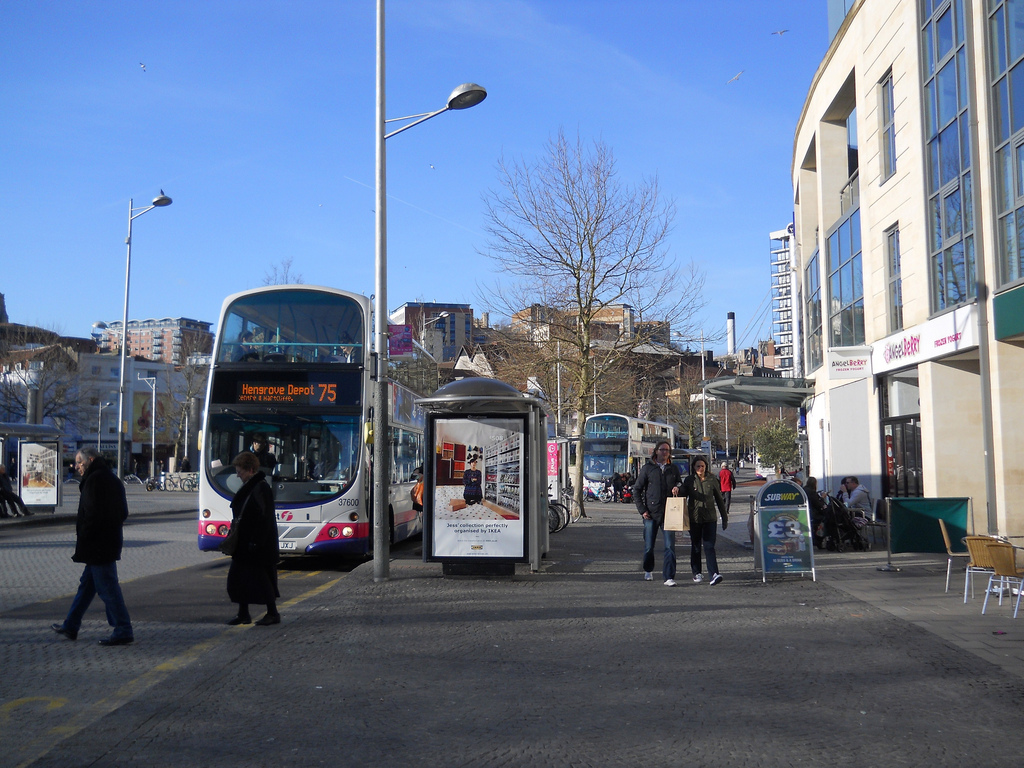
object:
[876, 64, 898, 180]
window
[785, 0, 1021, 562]
building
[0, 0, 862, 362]
sky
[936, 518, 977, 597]
chair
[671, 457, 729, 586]
people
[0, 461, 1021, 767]
street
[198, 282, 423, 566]
bus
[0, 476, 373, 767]
road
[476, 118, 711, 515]
tree